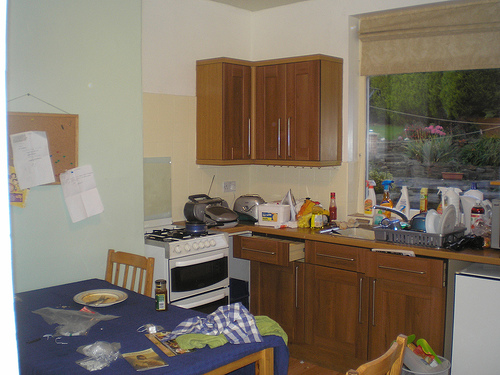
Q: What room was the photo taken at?
A: It was taken at the kitchen.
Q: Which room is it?
A: It is a kitchen.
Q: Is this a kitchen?
A: Yes, it is a kitchen.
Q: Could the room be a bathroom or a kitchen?
A: It is a kitchen.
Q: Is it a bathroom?
A: No, it is a kitchen.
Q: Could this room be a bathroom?
A: No, it is a kitchen.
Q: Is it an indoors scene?
A: Yes, it is indoors.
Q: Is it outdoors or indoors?
A: It is indoors.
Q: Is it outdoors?
A: No, it is indoors.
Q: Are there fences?
A: No, there are no fences.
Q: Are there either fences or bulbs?
A: No, there are no fences or bulbs.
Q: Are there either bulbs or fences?
A: No, there are no fences or bulbs.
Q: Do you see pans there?
A: Yes, there is a pan.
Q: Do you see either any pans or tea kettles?
A: Yes, there is a pan.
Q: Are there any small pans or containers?
A: Yes, there is a small pan.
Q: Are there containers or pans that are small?
A: Yes, the pan is small.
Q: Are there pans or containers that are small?
A: Yes, the pan is small.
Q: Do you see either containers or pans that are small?
A: Yes, the pan is small.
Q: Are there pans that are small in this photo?
A: Yes, there is a small pan.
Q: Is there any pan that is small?
A: Yes, there is a pan that is small.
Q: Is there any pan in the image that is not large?
A: Yes, there is a small pan.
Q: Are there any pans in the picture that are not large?
A: Yes, there is a small pan.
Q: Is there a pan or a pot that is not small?
A: No, there is a pan but it is small.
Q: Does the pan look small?
A: Yes, the pan is small.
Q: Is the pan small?
A: Yes, the pan is small.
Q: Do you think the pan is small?
A: Yes, the pan is small.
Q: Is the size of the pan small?
A: Yes, the pan is small.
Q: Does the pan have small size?
A: Yes, the pan is small.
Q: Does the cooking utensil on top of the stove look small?
A: Yes, the pan is small.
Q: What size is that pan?
A: The pan is small.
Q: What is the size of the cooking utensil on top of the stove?
A: The pan is small.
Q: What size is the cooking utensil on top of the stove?
A: The pan is small.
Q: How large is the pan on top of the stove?
A: The pan is small.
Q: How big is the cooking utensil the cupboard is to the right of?
A: The pan is small.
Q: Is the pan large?
A: No, the pan is small.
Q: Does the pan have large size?
A: No, the pan is small.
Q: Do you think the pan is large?
A: No, the pan is small.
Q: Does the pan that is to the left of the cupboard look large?
A: No, the pan is small.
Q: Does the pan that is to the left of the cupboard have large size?
A: No, the pan is small.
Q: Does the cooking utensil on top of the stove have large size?
A: No, the pan is small.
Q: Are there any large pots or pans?
A: No, there is a pan but it is small.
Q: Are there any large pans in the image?
A: No, there is a pan but it is small.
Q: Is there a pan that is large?
A: No, there is a pan but it is small.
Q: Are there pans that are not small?
A: No, there is a pan but it is small.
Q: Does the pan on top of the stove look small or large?
A: The pan is small.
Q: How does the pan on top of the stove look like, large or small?
A: The pan is small.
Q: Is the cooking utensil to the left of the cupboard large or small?
A: The pan is small.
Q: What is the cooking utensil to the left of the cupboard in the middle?
A: The cooking utensil is a pan.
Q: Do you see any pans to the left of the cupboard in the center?
A: Yes, there is a pan to the left of the cupboard.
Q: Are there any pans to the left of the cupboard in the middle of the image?
A: Yes, there is a pan to the left of the cupboard.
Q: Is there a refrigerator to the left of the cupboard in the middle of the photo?
A: No, there is a pan to the left of the cupboard.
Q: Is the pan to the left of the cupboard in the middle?
A: Yes, the pan is to the left of the cupboard.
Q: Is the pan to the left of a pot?
A: No, the pan is to the left of the cupboard.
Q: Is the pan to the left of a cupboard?
A: Yes, the pan is to the left of a cupboard.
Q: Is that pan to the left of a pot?
A: No, the pan is to the left of a cupboard.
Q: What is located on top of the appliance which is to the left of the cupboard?
A: The pan is on top of the stove.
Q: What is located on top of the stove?
A: The pan is on top of the stove.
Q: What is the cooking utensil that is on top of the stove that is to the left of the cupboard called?
A: The cooking utensil is a pan.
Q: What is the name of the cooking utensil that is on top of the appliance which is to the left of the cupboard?
A: The cooking utensil is a pan.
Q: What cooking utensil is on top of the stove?
A: The cooking utensil is a pan.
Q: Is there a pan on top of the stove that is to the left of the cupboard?
A: Yes, there is a pan on top of the stove.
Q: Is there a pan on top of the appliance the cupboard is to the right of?
A: Yes, there is a pan on top of the stove.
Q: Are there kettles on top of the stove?
A: No, there is a pan on top of the stove.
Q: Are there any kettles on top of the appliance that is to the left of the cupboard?
A: No, there is a pan on top of the stove.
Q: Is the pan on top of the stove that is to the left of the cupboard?
A: Yes, the pan is on top of the stove.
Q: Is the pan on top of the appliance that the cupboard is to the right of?
A: Yes, the pan is on top of the stove.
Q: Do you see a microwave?
A: No, there are no microwaves.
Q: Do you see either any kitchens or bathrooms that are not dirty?
A: No, there is a kitchen but it is dirty.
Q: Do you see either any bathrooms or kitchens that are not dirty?
A: No, there is a kitchen but it is dirty.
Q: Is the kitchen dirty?
A: Yes, the kitchen is dirty.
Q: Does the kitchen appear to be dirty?
A: Yes, the kitchen is dirty.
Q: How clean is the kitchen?
A: The kitchen is dirty.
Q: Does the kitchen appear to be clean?
A: No, the kitchen is dirty.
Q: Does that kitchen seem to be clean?
A: No, the kitchen is dirty.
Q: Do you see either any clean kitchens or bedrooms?
A: No, there is a kitchen but it is dirty.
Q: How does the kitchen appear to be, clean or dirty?
A: The kitchen is dirty.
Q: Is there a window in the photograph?
A: Yes, there is a window.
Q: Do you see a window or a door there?
A: Yes, there is a window.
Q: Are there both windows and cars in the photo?
A: No, there is a window but no cars.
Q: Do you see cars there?
A: No, there are no cars.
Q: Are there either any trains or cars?
A: No, there are no cars or trains.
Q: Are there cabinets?
A: Yes, there is a cabinet.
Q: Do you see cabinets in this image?
A: Yes, there is a cabinet.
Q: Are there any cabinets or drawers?
A: Yes, there is a cabinet.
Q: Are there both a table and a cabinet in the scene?
A: Yes, there are both a cabinet and a table.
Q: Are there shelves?
A: No, there are no shelves.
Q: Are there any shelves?
A: No, there are no shelves.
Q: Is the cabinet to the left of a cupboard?
A: Yes, the cabinet is to the left of a cupboard.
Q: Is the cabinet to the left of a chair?
A: No, the cabinet is to the left of a cupboard.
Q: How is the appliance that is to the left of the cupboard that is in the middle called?
A: The appliance is a stove.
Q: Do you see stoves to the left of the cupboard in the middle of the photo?
A: Yes, there is a stove to the left of the cupboard.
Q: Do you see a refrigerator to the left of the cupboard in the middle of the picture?
A: No, there is a stove to the left of the cupboard.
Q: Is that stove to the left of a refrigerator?
A: No, the stove is to the left of a cupboard.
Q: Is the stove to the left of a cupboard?
A: Yes, the stove is to the left of a cupboard.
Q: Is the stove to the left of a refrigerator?
A: No, the stove is to the left of a cupboard.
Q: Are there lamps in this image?
A: No, there are no lamps.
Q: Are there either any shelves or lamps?
A: No, there are no lamps or shelves.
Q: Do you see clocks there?
A: No, there are no clocks.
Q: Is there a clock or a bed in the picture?
A: No, there are no clocks or beds.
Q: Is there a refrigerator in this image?
A: No, there are no refrigerators.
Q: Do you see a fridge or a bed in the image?
A: No, there are no refrigerators or beds.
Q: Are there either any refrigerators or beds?
A: No, there are no refrigerators or beds.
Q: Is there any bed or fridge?
A: No, there are no refrigerators or beds.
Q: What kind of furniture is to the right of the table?
A: The piece of furniture is a cupboard.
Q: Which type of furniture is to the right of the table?
A: The piece of furniture is a cupboard.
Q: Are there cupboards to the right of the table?
A: Yes, there is a cupboard to the right of the table.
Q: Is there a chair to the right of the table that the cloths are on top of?
A: No, there is a cupboard to the right of the table.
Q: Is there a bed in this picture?
A: No, there are no beds.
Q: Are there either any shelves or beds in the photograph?
A: No, there are no beds or shelves.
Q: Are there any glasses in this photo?
A: No, there are no glasses.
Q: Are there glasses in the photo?
A: No, there are no glasses.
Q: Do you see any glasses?
A: No, there are no glasses.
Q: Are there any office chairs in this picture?
A: No, there are no office chairs.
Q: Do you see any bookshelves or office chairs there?
A: No, there are no office chairs or bookshelves.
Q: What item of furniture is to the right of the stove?
A: The piece of furniture is a cupboard.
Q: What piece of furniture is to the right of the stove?
A: The piece of furniture is a cupboard.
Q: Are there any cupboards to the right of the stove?
A: Yes, there is a cupboard to the right of the stove.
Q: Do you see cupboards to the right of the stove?
A: Yes, there is a cupboard to the right of the stove.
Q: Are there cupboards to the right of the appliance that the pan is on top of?
A: Yes, there is a cupboard to the right of the stove.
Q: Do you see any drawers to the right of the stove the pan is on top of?
A: No, there is a cupboard to the right of the stove.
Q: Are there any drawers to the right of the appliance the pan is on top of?
A: No, there is a cupboard to the right of the stove.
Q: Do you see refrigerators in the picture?
A: No, there are no refrigerators.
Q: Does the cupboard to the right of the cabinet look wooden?
A: Yes, the cupboard is wooden.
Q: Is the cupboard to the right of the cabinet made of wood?
A: Yes, the cupboard is made of wood.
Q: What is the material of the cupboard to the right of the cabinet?
A: The cupboard is made of wood.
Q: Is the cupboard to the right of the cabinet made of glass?
A: No, the cupboard is made of wood.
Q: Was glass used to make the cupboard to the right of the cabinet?
A: No, the cupboard is made of wood.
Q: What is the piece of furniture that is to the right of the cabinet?
A: The piece of furniture is a cupboard.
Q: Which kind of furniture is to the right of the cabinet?
A: The piece of furniture is a cupboard.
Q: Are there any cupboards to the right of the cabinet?
A: Yes, there is a cupboard to the right of the cabinet.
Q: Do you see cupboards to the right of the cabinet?
A: Yes, there is a cupboard to the right of the cabinet.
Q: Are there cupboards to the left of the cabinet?
A: No, the cupboard is to the right of the cabinet.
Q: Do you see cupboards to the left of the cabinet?
A: No, the cupboard is to the right of the cabinet.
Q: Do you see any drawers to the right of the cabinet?
A: No, there is a cupboard to the right of the cabinet.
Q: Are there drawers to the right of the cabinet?
A: No, there is a cupboard to the right of the cabinet.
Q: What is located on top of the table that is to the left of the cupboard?
A: The cloths are on top of the table.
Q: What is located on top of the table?
A: The cloths are on top of the table.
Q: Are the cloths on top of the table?
A: Yes, the cloths are on top of the table.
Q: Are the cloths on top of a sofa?
A: No, the cloths are on top of the table.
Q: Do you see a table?
A: Yes, there is a table.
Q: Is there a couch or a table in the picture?
A: Yes, there is a table.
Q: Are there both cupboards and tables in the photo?
A: Yes, there are both a table and cupboards.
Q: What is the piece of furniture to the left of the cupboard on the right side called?
A: The piece of furniture is a table.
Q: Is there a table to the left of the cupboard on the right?
A: Yes, there is a table to the left of the cupboard.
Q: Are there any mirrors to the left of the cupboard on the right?
A: No, there is a table to the left of the cupboard.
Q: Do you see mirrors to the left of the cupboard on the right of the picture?
A: No, there is a table to the left of the cupboard.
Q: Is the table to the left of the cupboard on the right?
A: Yes, the table is to the left of the cupboard.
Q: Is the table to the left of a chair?
A: No, the table is to the left of the cupboard.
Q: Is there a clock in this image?
A: No, there are no clocks.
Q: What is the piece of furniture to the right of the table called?
A: The piece of furniture is a cupboard.